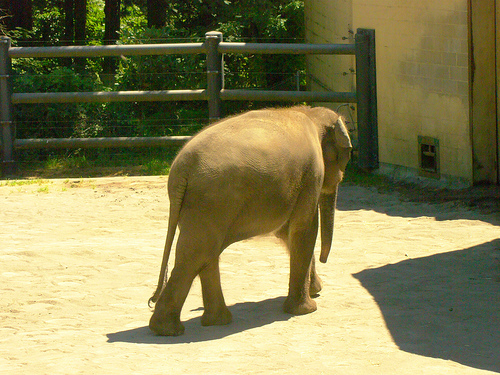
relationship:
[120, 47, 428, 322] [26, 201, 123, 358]
elephant on ground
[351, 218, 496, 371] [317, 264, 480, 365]
shadow on ground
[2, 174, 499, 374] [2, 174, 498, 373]
ground made of dirt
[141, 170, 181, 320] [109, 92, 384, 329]
tail oc elephant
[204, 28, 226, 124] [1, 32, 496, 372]
post of enclosoure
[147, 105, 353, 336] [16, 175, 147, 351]
elephant on ground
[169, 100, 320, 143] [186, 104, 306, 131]
hairs on back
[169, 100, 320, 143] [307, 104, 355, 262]
hairs on head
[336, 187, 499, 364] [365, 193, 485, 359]
shadows on ground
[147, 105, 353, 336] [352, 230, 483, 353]
elephant standing on shadow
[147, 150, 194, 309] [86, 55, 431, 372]
tail of elephant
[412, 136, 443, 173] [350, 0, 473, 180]
window bottom of brick wall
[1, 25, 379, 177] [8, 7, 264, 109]
fence in background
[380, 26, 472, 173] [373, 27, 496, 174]
bricks in wall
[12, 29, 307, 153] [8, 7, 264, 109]
trees in background